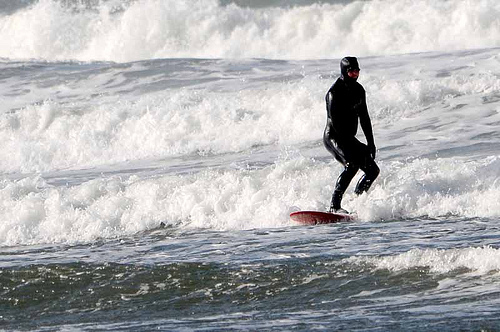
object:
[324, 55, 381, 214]
person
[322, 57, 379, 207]
wet suit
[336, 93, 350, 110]
black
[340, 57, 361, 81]
wet suit hood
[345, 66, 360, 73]
googles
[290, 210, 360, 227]
surfboard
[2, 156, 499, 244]
waves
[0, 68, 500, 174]
white caps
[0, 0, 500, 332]
water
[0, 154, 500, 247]
white foam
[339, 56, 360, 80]
head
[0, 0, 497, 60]
waves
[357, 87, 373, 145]
arm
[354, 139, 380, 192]
left leg